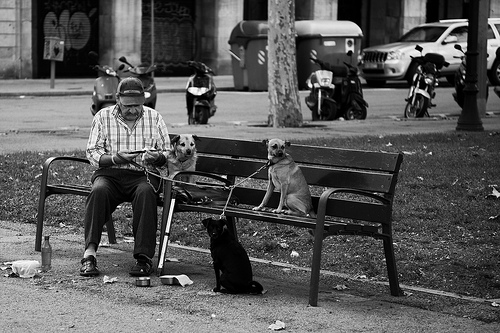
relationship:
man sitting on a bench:
[81, 78, 172, 276] [35, 134, 403, 307]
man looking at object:
[81, 78, 172, 276] [126, 149, 160, 154]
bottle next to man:
[40, 234, 51, 271] [81, 78, 172, 276]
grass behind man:
[35, 134, 403, 307] [81, 78, 172, 276]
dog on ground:
[201, 216, 264, 293] [0, 76, 499, 330]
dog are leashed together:
[202, 217, 264, 293] [164, 134, 316, 293]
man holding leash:
[81, 78, 172, 276] [115, 148, 272, 217]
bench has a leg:
[35, 134, 403, 307] [382, 235, 402, 296]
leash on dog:
[115, 148, 272, 217] [202, 217, 264, 293]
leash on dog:
[115, 148, 272, 217] [165, 134, 201, 186]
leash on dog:
[115, 148, 272, 217] [253, 139, 317, 218]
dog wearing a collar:
[253, 139, 317, 218] [266, 156, 288, 165]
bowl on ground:
[134, 274, 151, 288] [0, 76, 499, 330]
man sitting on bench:
[81, 78, 172, 276] [35, 134, 403, 307]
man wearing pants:
[81, 78, 172, 276] [84, 167, 162, 257]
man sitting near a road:
[81, 78, 172, 276] [1, 76, 498, 134]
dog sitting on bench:
[253, 139, 317, 218] [35, 134, 403, 307]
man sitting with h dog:
[81, 78, 172, 276] [202, 217, 264, 293]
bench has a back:
[35, 134, 403, 307] [170, 134, 403, 225]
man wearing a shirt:
[81, 78, 172, 276] [86, 103, 172, 173]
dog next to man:
[165, 134, 201, 186] [81, 78, 172, 276]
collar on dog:
[266, 156, 288, 165] [253, 139, 317, 218]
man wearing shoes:
[81, 78, 172, 276] [80, 254, 153, 277]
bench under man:
[35, 134, 403, 307] [81, 78, 172, 276]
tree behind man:
[266, 1, 303, 126] [81, 78, 172, 276]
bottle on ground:
[40, 234, 51, 271] [0, 76, 499, 330]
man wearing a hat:
[81, 78, 172, 276] [117, 75, 147, 106]